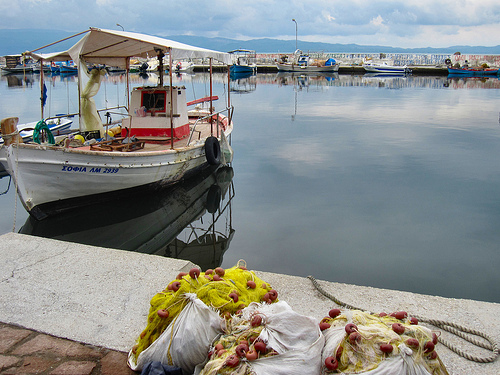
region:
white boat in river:
[15, 2, 226, 214]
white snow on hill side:
[375, 18, 437, 43]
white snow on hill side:
[328, 15, 398, 59]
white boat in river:
[27, 18, 221, 210]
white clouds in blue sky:
[451, 12, 492, 36]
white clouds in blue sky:
[210, 8, 278, 33]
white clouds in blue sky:
[330, 12, 401, 40]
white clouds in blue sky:
[315, 1, 346, 26]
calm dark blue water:
[284, 156, 339, 196]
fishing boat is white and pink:
[0, 20, 238, 219]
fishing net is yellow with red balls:
[119, 259, 284, 370]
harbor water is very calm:
[2, 55, 497, 304]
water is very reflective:
[2, 67, 497, 304]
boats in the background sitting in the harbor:
[3, 44, 498, 84]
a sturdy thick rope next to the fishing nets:
[305, 262, 498, 366]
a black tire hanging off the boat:
[200, 131, 227, 171]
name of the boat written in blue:
[58, 153, 120, 179]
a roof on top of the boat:
[28, 22, 239, 153]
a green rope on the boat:
[25, 115, 60, 145]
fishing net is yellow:
[151, 259, 286, 331]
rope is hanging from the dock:
[293, 272, 494, 369]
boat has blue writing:
[50, 152, 125, 184]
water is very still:
[234, 63, 479, 257]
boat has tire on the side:
[196, 140, 264, 182]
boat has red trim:
[108, 81, 238, 182]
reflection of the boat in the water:
[113, 159, 241, 271]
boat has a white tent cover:
[48, 18, 215, 125]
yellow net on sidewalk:
[133, 258, 310, 336]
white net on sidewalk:
[165, 303, 327, 373]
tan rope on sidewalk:
[307, 273, 492, 368]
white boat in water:
[26, 107, 238, 227]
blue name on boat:
[60, 159, 145, 179]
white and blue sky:
[265, 0, 397, 55]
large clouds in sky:
[213, 0, 405, 41]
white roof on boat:
[77, 3, 196, 63]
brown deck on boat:
[69, 107, 222, 165]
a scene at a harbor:
[13, 30, 493, 277]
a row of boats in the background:
[7, 43, 497, 91]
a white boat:
[0, 23, 255, 219]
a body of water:
[5, 85, 496, 286]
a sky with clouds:
[6, 0, 496, 70]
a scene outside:
[4, 17, 482, 372]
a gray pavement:
[8, 230, 498, 373]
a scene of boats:
[6, 35, 482, 299]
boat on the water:
[5, 26, 235, 212]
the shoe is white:
[279, 63, 331, 72]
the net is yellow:
[135, 261, 275, 346]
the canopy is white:
[27, 27, 220, 62]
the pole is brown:
[208, 56, 213, 134]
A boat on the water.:
[444, 57, 498, 80]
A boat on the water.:
[363, 59, 413, 74]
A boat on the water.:
[228, 48, 258, 79]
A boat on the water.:
[2, 25, 234, 217]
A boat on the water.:
[58, 62, 78, 77]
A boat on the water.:
[47, 60, 61, 75]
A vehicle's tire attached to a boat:
[206, 136, 221, 166]